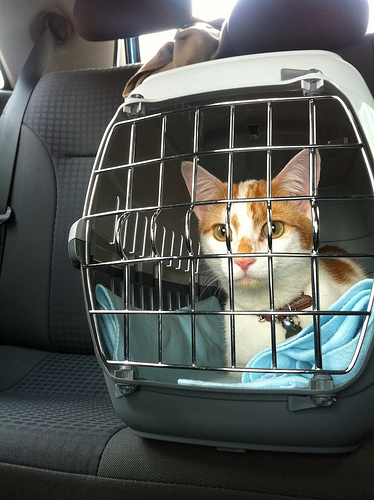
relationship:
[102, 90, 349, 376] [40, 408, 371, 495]
crate on a seat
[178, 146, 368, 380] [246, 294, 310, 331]
cat with a collar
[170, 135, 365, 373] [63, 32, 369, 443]
cat in crate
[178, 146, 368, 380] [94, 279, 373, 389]
cat laying on blanket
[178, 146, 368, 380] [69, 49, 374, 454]
cat inside crate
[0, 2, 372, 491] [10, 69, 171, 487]
car has seat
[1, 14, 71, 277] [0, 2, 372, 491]
seat belt in car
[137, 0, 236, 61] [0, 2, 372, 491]
window in car